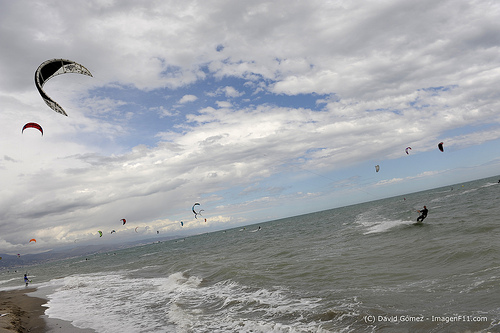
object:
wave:
[0, 266, 499, 332]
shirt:
[22, 276, 32, 285]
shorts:
[23, 282, 30, 287]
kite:
[20, 121, 45, 137]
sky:
[0, 0, 499, 257]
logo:
[358, 312, 487, 324]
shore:
[0, 282, 98, 333]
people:
[22, 273, 31, 288]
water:
[0, 175, 499, 332]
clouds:
[0, 0, 499, 255]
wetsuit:
[414, 209, 430, 225]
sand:
[0, 287, 97, 332]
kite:
[33, 57, 94, 118]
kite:
[435, 140, 443, 153]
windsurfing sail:
[118, 217, 127, 226]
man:
[413, 204, 429, 224]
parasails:
[372, 163, 382, 173]